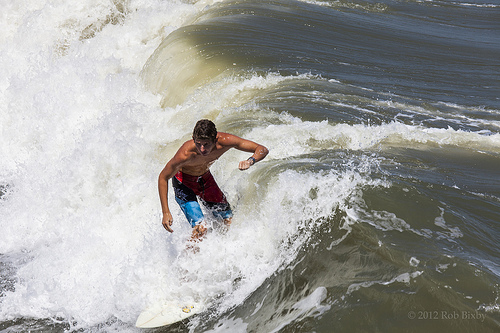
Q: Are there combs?
A: No, there are no combs.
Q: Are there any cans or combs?
A: No, there are no combs or cans.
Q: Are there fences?
A: No, there are no fences.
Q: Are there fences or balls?
A: No, there are no fences or balls.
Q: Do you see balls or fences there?
A: No, there are no fences or balls.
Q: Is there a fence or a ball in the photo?
A: No, there are no fences or balls.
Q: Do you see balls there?
A: No, there are no balls.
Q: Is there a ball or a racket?
A: No, there are no balls or rackets.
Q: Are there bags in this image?
A: No, there are no bags.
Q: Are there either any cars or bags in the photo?
A: No, there are no bags or cars.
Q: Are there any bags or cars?
A: No, there are no bags or cars.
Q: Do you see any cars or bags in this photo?
A: No, there are no bags or cars.